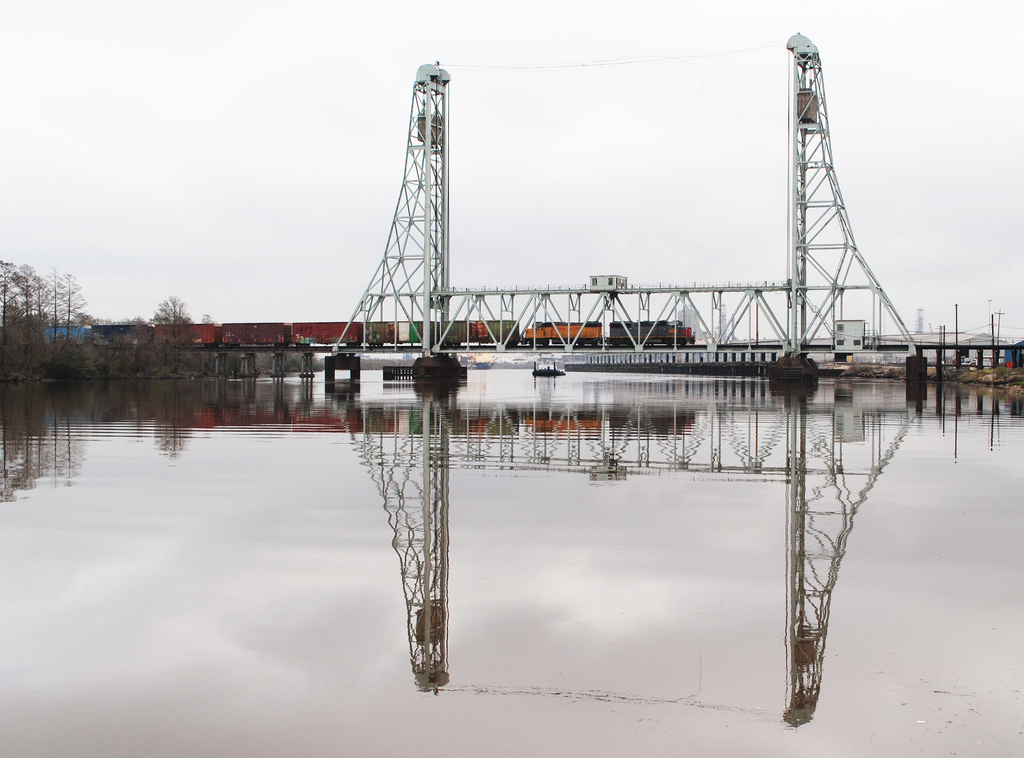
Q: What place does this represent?
A: It represents the lake.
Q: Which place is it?
A: It is a lake.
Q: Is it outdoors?
A: Yes, it is outdoors.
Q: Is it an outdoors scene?
A: Yes, it is outdoors.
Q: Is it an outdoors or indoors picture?
A: It is outdoors.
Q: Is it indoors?
A: No, it is outdoors.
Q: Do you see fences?
A: No, there are no fences.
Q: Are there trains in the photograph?
A: Yes, there is a train.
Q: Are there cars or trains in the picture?
A: Yes, there is a train.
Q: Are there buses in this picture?
A: No, there are no buses.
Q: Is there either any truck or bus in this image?
A: No, there are no buses or trucks.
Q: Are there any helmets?
A: No, there are no helmets.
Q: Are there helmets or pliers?
A: No, there are no helmets or pliers.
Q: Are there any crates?
A: No, there are no crates.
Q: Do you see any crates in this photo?
A: No, there are no crates.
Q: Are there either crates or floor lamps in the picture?
A: No, there are no crates or floor lamps.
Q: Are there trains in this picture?
A: Yes, there is a train.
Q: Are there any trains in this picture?
A: Yes, there is a train.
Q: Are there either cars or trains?
A: Yes, there is a train.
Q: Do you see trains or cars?
A: Yes, there is a train.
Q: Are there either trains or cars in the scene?
A: Yes, there is a train.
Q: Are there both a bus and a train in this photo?
A: No, there is a train but no buses.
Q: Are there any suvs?
A: No, there are no suvs.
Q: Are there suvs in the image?
A: No, there are no suvs.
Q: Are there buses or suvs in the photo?
A: No, there are no suvs or buses.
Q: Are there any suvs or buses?
A: No, there are no suvs or buses.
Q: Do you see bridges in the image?
A: Yes, there is a bridge.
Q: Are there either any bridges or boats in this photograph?
A: Yes, there is a bridge.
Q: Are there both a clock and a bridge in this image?
A: No, there is a bridge but no clocks.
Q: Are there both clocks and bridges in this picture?
A: No, there is a bridge but no clocks.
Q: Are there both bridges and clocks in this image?
A: No, there is a bridge but no clocks.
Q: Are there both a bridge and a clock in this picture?
A: No, there is a bridge but no clocks.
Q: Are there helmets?
A: No, there are no helmets.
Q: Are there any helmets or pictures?
A: No, there are no helmets or pictures.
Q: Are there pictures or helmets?
A: No, there are no helmets or pictures.